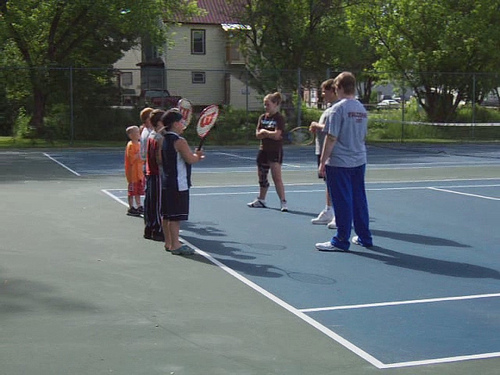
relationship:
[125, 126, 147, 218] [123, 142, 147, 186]
boy wearing a shirt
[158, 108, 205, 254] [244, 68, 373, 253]
boy are in front of adults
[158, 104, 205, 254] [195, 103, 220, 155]
boy holding racquet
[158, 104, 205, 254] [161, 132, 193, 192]
boy wearing a tank top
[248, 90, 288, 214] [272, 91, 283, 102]
woman has a ponytail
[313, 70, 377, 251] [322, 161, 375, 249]
adults wearing pants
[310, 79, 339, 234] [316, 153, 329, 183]
person wearing shorts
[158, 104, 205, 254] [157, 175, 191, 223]
boy wearing shorts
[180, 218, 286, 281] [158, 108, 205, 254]
shadow of boy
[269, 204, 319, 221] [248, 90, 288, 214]
shadow of woman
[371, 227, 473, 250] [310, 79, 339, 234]
shadow of person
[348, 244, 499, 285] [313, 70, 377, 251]
shadow of adults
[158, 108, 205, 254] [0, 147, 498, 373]
boy are on tennis court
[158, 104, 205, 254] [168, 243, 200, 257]
boy wearing clogs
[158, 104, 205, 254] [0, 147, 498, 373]
boy on tennis court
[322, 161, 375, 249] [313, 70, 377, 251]
pants are worn by adults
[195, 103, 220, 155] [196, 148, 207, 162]
racquet in h hands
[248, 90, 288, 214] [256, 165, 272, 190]
woman wearing a brace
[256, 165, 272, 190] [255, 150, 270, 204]
brace on her right leg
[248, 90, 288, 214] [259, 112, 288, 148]
woman wearing a t-shirt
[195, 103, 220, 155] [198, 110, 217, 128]
racquet has a w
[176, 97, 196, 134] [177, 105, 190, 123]
racquet has a w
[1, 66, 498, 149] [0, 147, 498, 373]
fence at edge of tennis court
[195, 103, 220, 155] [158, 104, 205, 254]
racquet being held by boy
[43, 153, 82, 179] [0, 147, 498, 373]
line on tennis court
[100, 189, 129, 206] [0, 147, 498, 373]
line on tennis court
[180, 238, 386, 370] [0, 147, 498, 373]
line on tennis court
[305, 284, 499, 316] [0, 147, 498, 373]
line on tennis court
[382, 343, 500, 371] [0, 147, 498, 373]
line on tennis court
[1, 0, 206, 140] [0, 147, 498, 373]
tree next to tennis court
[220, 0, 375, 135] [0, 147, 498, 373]
tree next to tennis court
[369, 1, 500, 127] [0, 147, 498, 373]
tree next to tennis court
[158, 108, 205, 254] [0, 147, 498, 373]
boy are standing on tennis court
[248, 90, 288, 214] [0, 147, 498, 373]
woman standing on tennis court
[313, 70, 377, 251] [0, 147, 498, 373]
adults standing on tennis court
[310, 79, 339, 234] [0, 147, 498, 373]
person standing on tennis court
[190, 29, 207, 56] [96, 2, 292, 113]
window on side of house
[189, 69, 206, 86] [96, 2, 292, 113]
window on side of house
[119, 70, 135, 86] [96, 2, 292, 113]
window on side of house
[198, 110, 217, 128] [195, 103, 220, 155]
w on racquet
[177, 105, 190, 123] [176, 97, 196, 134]
w on racquet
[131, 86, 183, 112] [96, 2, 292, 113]
truck parked by house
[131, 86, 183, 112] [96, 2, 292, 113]
truck in front of house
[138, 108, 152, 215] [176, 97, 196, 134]
boy holding racquet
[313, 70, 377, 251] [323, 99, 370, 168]
adults wearing a t-shirt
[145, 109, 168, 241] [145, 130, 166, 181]
boy wearing a shirt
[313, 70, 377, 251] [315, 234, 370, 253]
adults wearing tennis shoes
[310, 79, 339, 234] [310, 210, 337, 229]
person wearing tennis shoes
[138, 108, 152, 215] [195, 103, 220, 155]
boy holding racquet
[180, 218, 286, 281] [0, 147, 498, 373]
shadow on tennis court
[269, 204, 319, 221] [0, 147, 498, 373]
shadow on tennis court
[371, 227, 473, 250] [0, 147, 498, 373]
shadow on tennis court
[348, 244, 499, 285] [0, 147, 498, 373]
shadow on tennis court